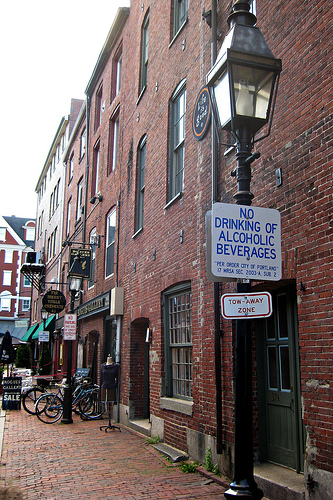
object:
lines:
[161, 282, 193, 301]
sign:
[2, 374, 22, 409]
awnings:
[29, 313, 56, 343]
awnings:
[22, 322, 38, 343]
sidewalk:
[0, 388, 229, 500]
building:
[109, 1, 332, 499]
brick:
[319, 160, 332, 174]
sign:
[62, 311, 78, 341]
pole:
[59, 288, 77, 426]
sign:
[218, 290, 272, 322]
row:
[20, 371, 106, 426]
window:
[184, 377, 190, 402]